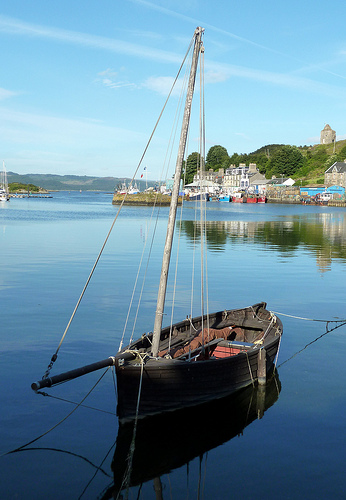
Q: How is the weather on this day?
A: It is cloudy.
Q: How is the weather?
A: It is cloudy.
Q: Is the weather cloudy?
A: Yes, it is cloudy.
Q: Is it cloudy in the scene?
A: Yes, it is cloudy.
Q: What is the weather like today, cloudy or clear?
A: It is cloudy.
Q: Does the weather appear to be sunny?
A: No, it is cloudy.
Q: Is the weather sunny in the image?
A: No, it is cloudy.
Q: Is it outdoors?
A: Yes, it is outdoors.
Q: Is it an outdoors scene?
A: Yes, it is outdoors.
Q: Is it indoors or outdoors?
A: It is outdoors.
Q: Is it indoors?
A: No, it is outdoors.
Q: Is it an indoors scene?
A: No, it is outdoors.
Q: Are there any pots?
A: No, there are no pots.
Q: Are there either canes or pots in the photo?
A: No, there are no pots or canes.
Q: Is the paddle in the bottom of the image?
A: Yes, the paddle is in the bottom of the image.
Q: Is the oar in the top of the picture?
A: No, the oar is in the bottom of the image.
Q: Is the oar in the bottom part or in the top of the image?
A: The oar is in the bottom of the image.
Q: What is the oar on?
A: The oar is on the ship.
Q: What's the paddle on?
A: The oar is on the ship.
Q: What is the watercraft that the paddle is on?
A: The watercraft is a ship.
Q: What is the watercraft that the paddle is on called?
A: The watercraft is a ship.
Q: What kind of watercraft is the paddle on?
A: The paddle is on the ship.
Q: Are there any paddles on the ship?
A: Yes, there is a paddle on the ship.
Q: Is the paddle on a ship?
A: Yes, the paddle is on a ship.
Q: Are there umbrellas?
A: No, there are no umbrellas.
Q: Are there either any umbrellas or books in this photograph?
A: No, there are no umbrellas or books.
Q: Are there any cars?
A: No, there are no cars.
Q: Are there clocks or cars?
A: No, there are no cars or clocks.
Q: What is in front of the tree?
A: The town is in front of the tree.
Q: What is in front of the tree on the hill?
A: The town is in front of the tree.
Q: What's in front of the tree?
A: The town is in front of the tree.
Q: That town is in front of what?
A: The town is in front of the tree.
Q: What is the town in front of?
A: The town is in front of the tree.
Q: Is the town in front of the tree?
A: Yes, the town is in front of the tree.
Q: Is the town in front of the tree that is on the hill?
A: Yes, the town is in front of the tree.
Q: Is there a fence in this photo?
A: No, there are no fences.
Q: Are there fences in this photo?
A: No, there are no fences.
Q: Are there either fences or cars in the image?
A: No, there are no fences or cars.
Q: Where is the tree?
A: The tree is on the hill.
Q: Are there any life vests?
A: No, there are no life vests.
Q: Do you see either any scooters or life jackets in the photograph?
A: No, there are no life jackets or scooters.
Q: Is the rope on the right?
A: Yes, the rope is on the right of the image.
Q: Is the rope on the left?
A: No, the rope is on the right of the image.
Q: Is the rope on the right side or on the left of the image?
A: The rope is on the right of the image.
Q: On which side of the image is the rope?
A: The rope is on the right of the image.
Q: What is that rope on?
A: The rope is on the ship.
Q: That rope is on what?
A: The rope is on the ship.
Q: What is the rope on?
A: The rope is on the ship.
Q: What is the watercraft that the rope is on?
A: The watercraft is a ship.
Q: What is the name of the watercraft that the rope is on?
A: The watercraft is a ship.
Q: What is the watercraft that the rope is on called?
A: The watercraft is a ship.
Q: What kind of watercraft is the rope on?
A: The rope is on the ship.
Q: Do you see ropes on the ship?
A: Yes, there is a rope on the ship.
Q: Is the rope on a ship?
A: Yes, the rope is on a ship.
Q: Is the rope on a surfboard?
A: No, the rope is on a ship.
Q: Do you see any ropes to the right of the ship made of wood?
A: Yes, there is a rope to the right of the ship.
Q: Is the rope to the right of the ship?
A: Yes, the rope is to the right of the ship.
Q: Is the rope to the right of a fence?
A: No, the rope is to the right of the ship.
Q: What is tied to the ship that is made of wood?
A: The rope is tied to the ship.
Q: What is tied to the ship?
A: The rope is tied to the ship.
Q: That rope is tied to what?
A: The rope is tied to the ship.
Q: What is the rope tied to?
A: The rope is tied to the ship.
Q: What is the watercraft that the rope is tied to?
A: The watercraft is a ship.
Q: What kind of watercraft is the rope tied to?
A: The rope is tied to the ship.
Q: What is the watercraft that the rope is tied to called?
A: The watercraft is a ship.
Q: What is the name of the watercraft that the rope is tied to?
A: The watercraft is a ship.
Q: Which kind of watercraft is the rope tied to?
A: The rope is tied to the ship.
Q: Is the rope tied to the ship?
A: Yes, the rope is tied to the ship.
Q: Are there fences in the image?
A: No, there are no fences.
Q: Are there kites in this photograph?
A: No, there are no kites.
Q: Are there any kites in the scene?
A: No, there are no kites.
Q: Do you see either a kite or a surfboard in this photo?
A: No, there are no kites or surfboards.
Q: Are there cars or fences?
A: No, there are no cars or fences.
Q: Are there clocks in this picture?
A: No, there are no clocks.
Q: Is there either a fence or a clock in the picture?
A: No, there are no clocks or fences.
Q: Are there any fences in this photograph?
A: No, there are no fences.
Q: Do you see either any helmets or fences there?
A: No, there are no fences or helmets.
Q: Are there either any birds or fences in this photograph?
A: No, there are no fences or birds.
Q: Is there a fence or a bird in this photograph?
A: No, there are no fences or birds.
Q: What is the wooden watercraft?
A: The watercraft is a ship.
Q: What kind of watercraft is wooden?
A: The watercraft is a ship.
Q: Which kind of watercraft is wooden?
A: The watercraft is a ship.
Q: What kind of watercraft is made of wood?
A: The watercraft is a ship.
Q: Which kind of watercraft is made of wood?
A: The watercraft is a ship.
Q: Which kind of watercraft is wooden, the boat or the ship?
A: The ship is wooden.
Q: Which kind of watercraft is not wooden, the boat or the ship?
A: The boat is not wooden.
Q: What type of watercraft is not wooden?
A: The watercraft is a boat.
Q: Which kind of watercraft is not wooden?
A: The watercraft is a boat.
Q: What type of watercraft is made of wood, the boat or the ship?
A: The ship is made of wood.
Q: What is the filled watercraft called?
A: The watercraft is a ship.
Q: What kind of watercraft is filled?
A: The watercraft is a ship.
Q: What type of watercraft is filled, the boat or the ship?
A: The ship is filled.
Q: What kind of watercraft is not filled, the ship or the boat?
A: The boat is not filled.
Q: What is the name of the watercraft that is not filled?
A: The watercraft is a boat.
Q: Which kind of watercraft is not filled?
A: The watercraft is a boat.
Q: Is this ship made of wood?
A: Yes, the ship is made of wood.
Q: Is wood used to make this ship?
A: Yes, the ship is made of wood.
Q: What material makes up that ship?
A: The ship is made of wood.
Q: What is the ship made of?
A: The ship is made of wood.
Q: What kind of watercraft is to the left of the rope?
A: The watercraft is a ship.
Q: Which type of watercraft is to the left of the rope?
A: The watercraft is a ship.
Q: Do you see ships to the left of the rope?
A: Yes, there is a ship to the left of the rope.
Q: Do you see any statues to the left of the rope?
A: No, there is a ship to the left of the rope.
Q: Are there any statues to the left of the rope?
A: No, there is a ship to the left of the rope.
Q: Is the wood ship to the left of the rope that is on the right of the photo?
A: Yes, the ship is to the left of the rope.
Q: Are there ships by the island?
A: Yes, there is a ship by the island.